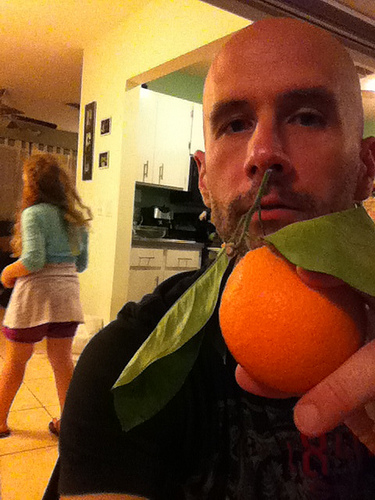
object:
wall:
[76, 6, 263, 351]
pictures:
[78, 93, 120, 189]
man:
[45, 10, 374, 498]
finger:
[291, 338, 375, 440]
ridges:
[323, 376, 358, 408]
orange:
[219, 239, 372, 385]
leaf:
[113, 245, 230, 391]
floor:
[0, 340, 52, 498]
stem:
[112, 161, 272, 390]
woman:
[1, 145, 92, 459]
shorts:
[2, 323, 82, 347]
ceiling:
[1, 0, 186, 51]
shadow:
[4, 41, 82, 102]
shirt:
[2, 263, 93, 327]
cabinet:
[139, 87, 186, 189]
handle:
[155, 160, 168, 184]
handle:
[140, 159, 151, 182]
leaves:
[264, 206, 375, 302]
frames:
[85, 102, 92, 179]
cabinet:
[141, 87, 205, 191]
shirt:
[53, 253, 372, 500]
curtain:
[0, 138, 77, 252]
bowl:
[133, 222, 172, 238]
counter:
[127, 241, 205, 311]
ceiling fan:
[0, 83, 59, 135]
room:
[0, 0, 111, 320]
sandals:
[47, 416, 68, 442]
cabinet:
[127, 247, 164, 299]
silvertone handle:
[152, 274, 162, 290]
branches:
[225, 167, 273, 256]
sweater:
[13, 203, 93, 272]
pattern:
[197, 343, 373, 500]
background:
[0, 0, 191, 500]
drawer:
[130, 247, 164, 267]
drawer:
[166, 250, 198, 270]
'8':
[303, 426, 331, 482]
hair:
[26, 146, 90, 246]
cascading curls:
[4, 182, 97, 275]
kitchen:
[130, 60, 372, 310]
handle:
[134, 254, 160, 265]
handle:
[173, 256, 194, 265]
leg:
[2, 335, 39, 439]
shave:
[226, 175, 316, 226]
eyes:
[213, 104, 255, 146]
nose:
[241, 99, 299, 181]